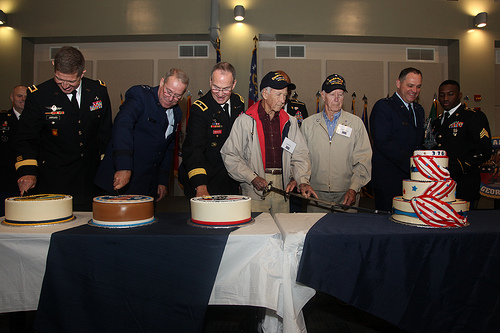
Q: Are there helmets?
A: No, there are no helmets.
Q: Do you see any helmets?
A: No, there are no helmets.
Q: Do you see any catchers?
A: No, there are no catchers.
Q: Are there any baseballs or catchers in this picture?
A: No, there are no catchers or baseballs.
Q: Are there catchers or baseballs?
A: No, there are no catchers or baseballs.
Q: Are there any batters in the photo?
A: No, there are no batters.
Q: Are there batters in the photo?
A: No, there are no batters.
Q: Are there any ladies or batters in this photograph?
A: No, there are no batters or ladies.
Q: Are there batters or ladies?
A: No, there are no batters or ladies.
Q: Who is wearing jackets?
A: The men are wearing jackets.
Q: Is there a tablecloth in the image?
A: Yes, there is a tablecloth.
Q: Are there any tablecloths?
A: Yes, there is a tablecloth.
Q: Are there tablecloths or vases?
A: Yes, there is a tablecloth.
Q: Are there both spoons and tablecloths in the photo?
A: No, there is a tablecloth but no spoons.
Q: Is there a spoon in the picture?
A: No, there are no spoons.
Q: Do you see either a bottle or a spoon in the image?
A: No, there are no spoons or bottles.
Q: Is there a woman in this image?
A: No, there are no women.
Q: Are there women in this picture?
A: No, there are no women.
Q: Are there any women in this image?
A: No, there are no women.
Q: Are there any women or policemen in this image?
A: No, there are no women or policemen.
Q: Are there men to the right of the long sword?
A: Yes, there is a man to the right of the sword.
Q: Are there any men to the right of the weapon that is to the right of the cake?
A: Yes, there is a man to the right of the sword.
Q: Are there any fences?
A: No, there are no fences.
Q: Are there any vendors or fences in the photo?
A: No, there are no fences or vendors.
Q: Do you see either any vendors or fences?
A: No, there are no fences or vendors.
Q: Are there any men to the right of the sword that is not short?
A: Yes, there is a man to the right of the sword.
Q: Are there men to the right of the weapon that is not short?
A: Yes, there is a man to the right of the sword.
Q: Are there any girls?
A: No, there are no girls.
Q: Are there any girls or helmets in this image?
A: No, there are no girls or helmets.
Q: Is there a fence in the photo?
A: No, there are no fences.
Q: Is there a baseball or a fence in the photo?
A: No, there are no fences or baseballs.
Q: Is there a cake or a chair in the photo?
A: Yes, there is a cake.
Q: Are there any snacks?
A: No, there are no snacks.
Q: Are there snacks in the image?
A: No, there are no snacks.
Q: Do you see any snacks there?
A: No, there are no snacks.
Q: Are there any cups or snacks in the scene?
A: No, there are no snacks or cups.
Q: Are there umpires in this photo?
A: No, there are no umpires.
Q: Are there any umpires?
A: No, there are no umpires.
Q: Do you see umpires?
A: No, there are no umpires.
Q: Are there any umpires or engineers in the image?
A: No, there are no umpires or engineers.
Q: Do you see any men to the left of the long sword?
A: Yes, there is a man to the left of the sword.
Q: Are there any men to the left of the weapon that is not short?
A: Yes, there is a man to the left of the sword.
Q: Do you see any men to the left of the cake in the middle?
A: Yes, there is a man to the left of the cake.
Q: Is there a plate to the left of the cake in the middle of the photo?
A: No, there is a man to the left of the cake.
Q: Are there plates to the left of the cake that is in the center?
A: No, there is a man to the left of the cake.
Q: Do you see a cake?
A: Yes, there is a cake.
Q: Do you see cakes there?
A: Yes, there is a cake.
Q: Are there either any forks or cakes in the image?
A: Yes, there is a cake.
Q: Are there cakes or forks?
A: Yes, there is a cake.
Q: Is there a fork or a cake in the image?
A: Yes, there is a cake.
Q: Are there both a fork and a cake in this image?
A: No, there is a cake but no forks.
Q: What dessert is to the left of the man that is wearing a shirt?
A: The dessert is a cake.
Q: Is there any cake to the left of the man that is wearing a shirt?
A: Yes, there is a cake to the left of the man.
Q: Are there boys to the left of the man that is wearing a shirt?
A: No, there is a cake to the left of the man.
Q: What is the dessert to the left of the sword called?
A: The dessert is a cake.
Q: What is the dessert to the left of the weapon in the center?
A: The dessert is a cake.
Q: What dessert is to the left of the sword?
A: The dessert is a cake.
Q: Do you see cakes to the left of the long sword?
A: Yes, there is a cake to the left of the sword.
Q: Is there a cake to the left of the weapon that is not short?
A: Yes, there is a cake to the left of the sword.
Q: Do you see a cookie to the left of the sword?
A: No, there is a cake to the left of the sword.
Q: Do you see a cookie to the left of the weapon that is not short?
A: No, there is a cake to the left of the sword.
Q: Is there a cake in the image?
A: Yes, there is a cake.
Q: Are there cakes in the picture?
A: Yes, there is a cake.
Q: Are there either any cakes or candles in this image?
A: Yes, there is a cake.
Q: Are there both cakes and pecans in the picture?
A: No, there is a cake but no pecans.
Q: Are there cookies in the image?
A: No, there are no cookies.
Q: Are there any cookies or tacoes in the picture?
A: No, there are no cookies or tacoes.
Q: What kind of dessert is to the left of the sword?
A: The dessert is a cake.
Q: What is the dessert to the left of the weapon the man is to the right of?
A: The dessert is a cake.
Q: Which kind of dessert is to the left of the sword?
A: The dessert is a cake.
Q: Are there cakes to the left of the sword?
A: Yes, there is a cake to the left of the sword.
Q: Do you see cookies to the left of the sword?
A: No, there is a cake to the left of the sword.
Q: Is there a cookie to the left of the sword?
A: No, there is a cake to the left of the sword.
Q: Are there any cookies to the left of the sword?
A: No, there is a cake to the left of the sword.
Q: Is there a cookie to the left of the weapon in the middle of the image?
A: No, there is a cake to the left of the sword.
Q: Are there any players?
A: No, there are no players.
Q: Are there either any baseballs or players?
A: No, there are no players or baseballs.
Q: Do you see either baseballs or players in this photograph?
A: No, there are no players or baseballs.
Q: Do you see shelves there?
A: No, there are no shelves.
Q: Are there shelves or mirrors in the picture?
A: No, there are no shelves or mirrors.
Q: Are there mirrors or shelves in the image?
A: No, there are no shelves or mirrors.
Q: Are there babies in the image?
A: No, there are no babies.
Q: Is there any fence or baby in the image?
A: No, there are no babies or fences.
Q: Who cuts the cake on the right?
A: The man cuts the cake.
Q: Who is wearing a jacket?
A: The man is wearing a jacket.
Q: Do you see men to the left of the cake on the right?
A: Yes, there is a man to the left of the cake.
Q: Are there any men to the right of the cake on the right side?
A: No, the man is to the left of the cake.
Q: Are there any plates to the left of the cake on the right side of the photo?
A: No, there is a man to the left of the cake.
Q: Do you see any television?
A: No, there are no televisions.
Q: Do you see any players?
A: No, there are no players.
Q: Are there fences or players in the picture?
A: No, there are no players or fences.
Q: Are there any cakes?
A: Yes, there is a cake.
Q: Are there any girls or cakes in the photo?
A: Yes, there is a cake.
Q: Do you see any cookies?
A: No, there are no cookies.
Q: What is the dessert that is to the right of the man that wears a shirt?
A: The dessert is a cake.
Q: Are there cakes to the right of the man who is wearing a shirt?
A: Yes, there is a cake to the right of the man.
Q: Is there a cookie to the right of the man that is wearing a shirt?
A: No, there is a cake to the right of the man.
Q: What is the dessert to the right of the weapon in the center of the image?
A: The dessert is a cake.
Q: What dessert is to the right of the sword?
A: The dessert is a cake.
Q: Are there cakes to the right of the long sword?
A: Yes, there is a cake to the right of the sword.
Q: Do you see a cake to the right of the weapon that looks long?
A: Yes, there is a cake to the right of the sword.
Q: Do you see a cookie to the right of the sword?
A: No, there is a cake to the right of the sword.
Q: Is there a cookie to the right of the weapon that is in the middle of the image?
A: No, there is a cake to the right of the sword.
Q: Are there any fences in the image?
A: No, there are no fences.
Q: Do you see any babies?
A: No, there are no babies.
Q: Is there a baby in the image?
A: No, there are no babies.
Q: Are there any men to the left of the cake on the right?
A: Yes, there is a man to the left of the cake.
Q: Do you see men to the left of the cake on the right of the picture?
A: Yes, there is a man to the left of the cake.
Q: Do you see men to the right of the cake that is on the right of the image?
A: No, the man is to the left of the cake.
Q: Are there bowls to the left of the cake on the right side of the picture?
A: No, there is a man to the left of the cake.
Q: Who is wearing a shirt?
A: The man is wearing a shirt.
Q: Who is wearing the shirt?
A: The man is wearing a shirt.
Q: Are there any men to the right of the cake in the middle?
A: Yes, there is a man to the right of the cake.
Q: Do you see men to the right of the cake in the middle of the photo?
A: Yes, there is a man to the right of the cake.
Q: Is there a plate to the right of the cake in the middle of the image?
A: No, there is a man to the right of the cake.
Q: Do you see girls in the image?
A: No, there are no girls.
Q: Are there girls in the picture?
A: No, there are no girls.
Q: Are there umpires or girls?
A: No, there are no girls or umpires.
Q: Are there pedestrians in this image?
A: No, there are no pedestrians.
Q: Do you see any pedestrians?
A: No, there are no pedestrians.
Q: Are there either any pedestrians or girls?
A: No, there are no pedestrians or girls.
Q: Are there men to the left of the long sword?
A: Yes, there is a man to the left of the sword.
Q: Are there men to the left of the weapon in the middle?
A: Yes, there is a man to the left of the sword.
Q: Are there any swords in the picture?
A: Yes, there is a sword.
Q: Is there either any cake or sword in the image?
A: Yes, there is a sword.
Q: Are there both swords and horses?
A: No, there is a sword but no horses.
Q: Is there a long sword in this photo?
A: Yes, there is a long sword.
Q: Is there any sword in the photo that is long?
A: Yes, there is a sword that is long.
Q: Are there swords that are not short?
A: Yes, there is a long sword.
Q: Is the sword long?
A: Yes, the sword is long.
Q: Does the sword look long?
A: Yes, the sword is long.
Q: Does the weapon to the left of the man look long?
A: Yes, the sword is long.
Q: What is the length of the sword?
A: The sword is long.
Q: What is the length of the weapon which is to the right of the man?
A: The sword is long.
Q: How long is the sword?
A: The sword is long.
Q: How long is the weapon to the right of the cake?
A: The sword is long.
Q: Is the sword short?
A: No, the sword is long.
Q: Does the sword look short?
A: No, the sword is long.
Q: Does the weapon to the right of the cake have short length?
A: No, the sword is long.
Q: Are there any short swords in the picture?
A: No, there is a sword but it is long.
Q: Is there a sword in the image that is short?
A: No, there is a sword but it is long.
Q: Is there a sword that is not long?
A: No, there is a sword but it is long.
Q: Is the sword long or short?
A: The sword is long.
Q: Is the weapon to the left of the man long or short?
A: The sword is long.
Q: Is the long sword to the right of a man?
A: Yes, the sword is to the right of a man.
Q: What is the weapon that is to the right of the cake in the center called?
A: The weapon is a sword.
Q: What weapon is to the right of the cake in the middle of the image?
A: The weapon is a sword.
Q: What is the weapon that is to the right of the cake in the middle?
A: The weapon is a sword.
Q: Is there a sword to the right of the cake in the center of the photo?
A: Yes, there is a sword to the right of the cake.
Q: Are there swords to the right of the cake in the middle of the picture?
A: Yes, there is a sword to the right of the cake.